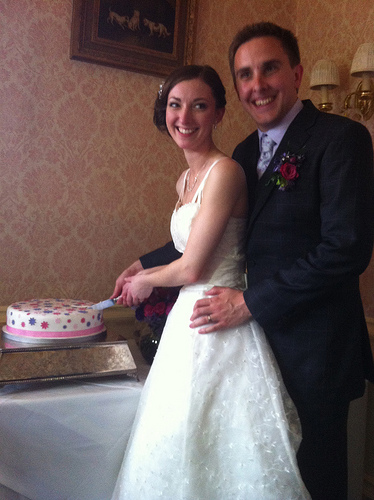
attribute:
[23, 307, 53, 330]
stars — colored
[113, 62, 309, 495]
woman — smiling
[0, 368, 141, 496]
tablecloth — white 